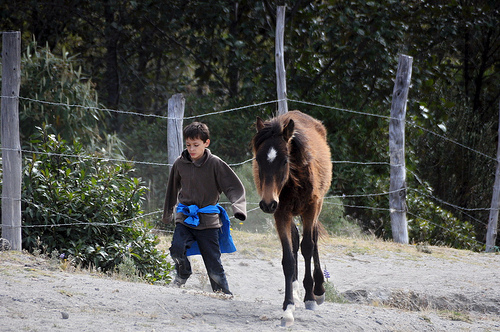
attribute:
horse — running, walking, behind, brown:
[234, 110, 336, 323]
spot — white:
[266, 143, 278, 162]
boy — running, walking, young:
[158, 118, 244, 300]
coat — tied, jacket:
[175, 203, 233, 251]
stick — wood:
[1, 29, 23, 250]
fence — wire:
[190, 95, 280, 115]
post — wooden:
[2, 30, 28, 251]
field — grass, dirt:
[327, 233, 497, 328]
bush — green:
[44, 144, 162, 276]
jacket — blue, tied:
[175, 196, 241, 257]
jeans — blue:
[171, 222, 225, 290]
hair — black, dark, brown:
[186, 124, 211, 140]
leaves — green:
[48, 167, 123, 203]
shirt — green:
[164, 151, 227, 205]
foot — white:
[284, 306, 296, 323]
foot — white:
[302, 297, 315, 309]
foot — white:
[317, 289, 327, 307]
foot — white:
[289, 274, 299, 292]